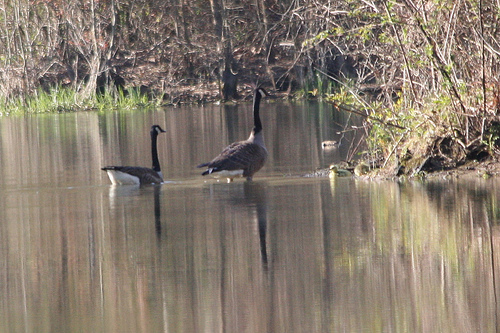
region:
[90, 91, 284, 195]
two ducks on water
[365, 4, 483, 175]
brown bushes next to water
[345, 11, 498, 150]
bushes have thin branches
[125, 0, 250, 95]
brown ground behind water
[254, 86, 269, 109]
white stripe on face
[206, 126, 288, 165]
duck has brown body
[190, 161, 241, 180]
black and white tail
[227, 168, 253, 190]
duck has brown feet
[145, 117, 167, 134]
head of a bird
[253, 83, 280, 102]
head of a bird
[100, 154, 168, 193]
body of a bird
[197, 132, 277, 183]
body of a bird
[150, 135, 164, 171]
neck of a bird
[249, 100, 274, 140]
neck of a bird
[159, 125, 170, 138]
peck of a bird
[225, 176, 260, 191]
leg of a bird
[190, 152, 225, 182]
feather of a bird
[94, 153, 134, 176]
feathers of a bird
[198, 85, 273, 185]
a black and white swan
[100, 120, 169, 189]
a black and white swan swimming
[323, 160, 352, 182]
a baby duck in the water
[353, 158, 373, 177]
a baby duck in the water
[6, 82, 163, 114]
grass growing on the shore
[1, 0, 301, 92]
dead vegetation on the shore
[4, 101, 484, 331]
a small body of water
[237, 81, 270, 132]
black neck of a swan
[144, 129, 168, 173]
black neck of a swan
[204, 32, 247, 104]
a dead tree trunk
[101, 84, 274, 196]
These animals have long necks.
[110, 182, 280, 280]
The reflections are distorted on the water.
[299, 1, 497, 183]
Plant growth is next to the water.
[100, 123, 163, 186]
This animal is resting on the water.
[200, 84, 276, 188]
This animal is standing in the water.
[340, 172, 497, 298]
The brush is reflected on the surface of the water.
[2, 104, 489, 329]
The water is still with little ripples.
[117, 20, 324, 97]
Fallen leaves are scattered on the bank.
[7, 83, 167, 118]
A small patch of grass grows into the water.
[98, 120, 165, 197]
This animal is darkly colored with white accents.